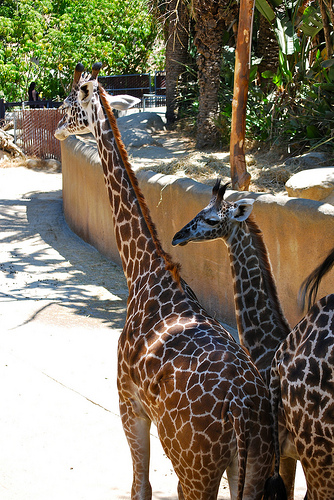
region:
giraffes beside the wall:
[40, 55, 292, 445]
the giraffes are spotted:
[34, 46, 292, 483]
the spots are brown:
[139, 301, 202, 395]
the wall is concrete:
[45, 133, 329, 312]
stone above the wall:
[277, 139, 333, 207]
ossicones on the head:
[69, 51, 104, 86]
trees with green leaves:
[4, 2, 133, 64]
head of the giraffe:
[168, 176, 257, 245]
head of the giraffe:
[35, 77, 135, 150]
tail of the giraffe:
[266, 378, 290, 497]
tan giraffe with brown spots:
[50, 61, 279, 498]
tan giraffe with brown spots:
[168, 174, 303, 385]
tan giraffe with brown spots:
[267, 287, 332, 497]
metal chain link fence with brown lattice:
[1, 101, 66, 158]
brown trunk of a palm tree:
[191, 11, 220, 147]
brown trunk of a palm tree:
[154, 4, 188, 130]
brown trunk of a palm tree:
[247, 7, 281, 108]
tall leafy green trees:
[2, 0, 152, 104]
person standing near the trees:
[26, 77, 43, 108]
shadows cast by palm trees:
[1, 187, 134, 331]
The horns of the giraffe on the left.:
[74, 60, 99, 80]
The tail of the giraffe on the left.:
[236, 413, 247, 497]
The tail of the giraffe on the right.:
[272, 371, 286, 490]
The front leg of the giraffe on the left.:
[120, 400, 152, 495]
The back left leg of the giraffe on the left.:
[171, 452, 216, 496]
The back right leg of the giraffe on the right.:
[236, 442, 264, 496]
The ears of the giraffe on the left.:
[76, 83, 140, 112]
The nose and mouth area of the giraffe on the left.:
[55, 123, 66, 141]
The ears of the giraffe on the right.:
[223, 197, 254, 218]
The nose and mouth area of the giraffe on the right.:
[171, 228, 188, 245]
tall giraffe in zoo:
[60, 93, 235, 488]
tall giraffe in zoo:
[232, 234, 270, 332]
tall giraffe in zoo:
[299, 328, 323, 430]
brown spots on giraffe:
[129, 340, 217, 419]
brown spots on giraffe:
[251, 278, 267, 314]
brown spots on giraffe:
[290, 358, 321, 397]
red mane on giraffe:
[109, 106, 167, 222]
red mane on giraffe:
[261, 246, 294, 318]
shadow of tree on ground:
[10, 198, 66, 313]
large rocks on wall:
[273, 159, 324, 179]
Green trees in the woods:
[0, 1, 165, 112]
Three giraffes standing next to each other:
[35, 57, 330, 492]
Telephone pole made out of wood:
[220, 3, 273, 222]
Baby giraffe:
[198, 160, 323, 498]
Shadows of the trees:
[2, 166, 122, 339]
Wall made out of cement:
[48, 74, 327, 336]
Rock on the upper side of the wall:
[280, 149, 331, 212]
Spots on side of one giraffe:
[139, 295, 210, 403]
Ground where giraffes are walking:
[3, 149, 120, 480]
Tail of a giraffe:
[221, 397, 255, 495]